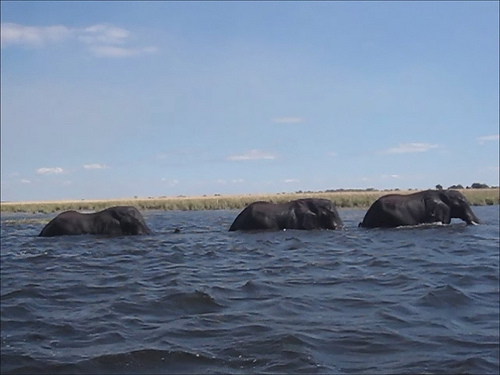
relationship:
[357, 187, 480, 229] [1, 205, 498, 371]
elephant in water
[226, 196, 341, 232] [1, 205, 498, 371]
elephant in water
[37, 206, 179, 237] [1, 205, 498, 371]
elephant in water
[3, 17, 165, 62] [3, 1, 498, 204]
clouds are in sky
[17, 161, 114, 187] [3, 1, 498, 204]
clouds are in sky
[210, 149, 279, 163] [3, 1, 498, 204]
clouds are in sky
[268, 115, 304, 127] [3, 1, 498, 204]
clouds are in sky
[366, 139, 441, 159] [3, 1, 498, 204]
clouds are in sky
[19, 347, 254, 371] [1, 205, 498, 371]
waves are in water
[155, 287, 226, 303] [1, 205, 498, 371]
waves are in water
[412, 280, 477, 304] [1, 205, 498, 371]
waves are in water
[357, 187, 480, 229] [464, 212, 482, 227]
elephant has a trunk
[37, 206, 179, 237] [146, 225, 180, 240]
elephant has a trunk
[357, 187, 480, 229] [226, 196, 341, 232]
elephant i front of an elephant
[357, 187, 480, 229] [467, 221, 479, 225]
elephant has tusk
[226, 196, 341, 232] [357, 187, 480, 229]
elephant behind an elephant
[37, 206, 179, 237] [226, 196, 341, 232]
elephant behind an elephant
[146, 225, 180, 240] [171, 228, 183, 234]
trunk has an end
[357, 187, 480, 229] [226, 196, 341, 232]
elephant in front of an elephant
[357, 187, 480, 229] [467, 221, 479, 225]
elephant has a tusk